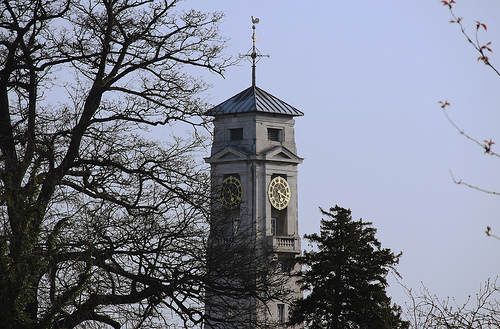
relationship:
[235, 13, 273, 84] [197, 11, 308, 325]
rod on top of clock tower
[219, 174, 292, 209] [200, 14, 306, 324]
clocks on either side of tower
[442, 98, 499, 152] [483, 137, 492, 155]
branch has leaves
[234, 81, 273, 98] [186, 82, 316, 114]
spot on roof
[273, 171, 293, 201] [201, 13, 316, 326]
clock on top of tower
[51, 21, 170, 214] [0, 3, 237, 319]
branches on tree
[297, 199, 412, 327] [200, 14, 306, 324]
tree by tower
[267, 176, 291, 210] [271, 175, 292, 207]
clock has face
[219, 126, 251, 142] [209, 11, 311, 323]
window on top of tower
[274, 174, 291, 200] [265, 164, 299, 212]
hands on clock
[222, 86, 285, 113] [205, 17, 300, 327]
roof of tower